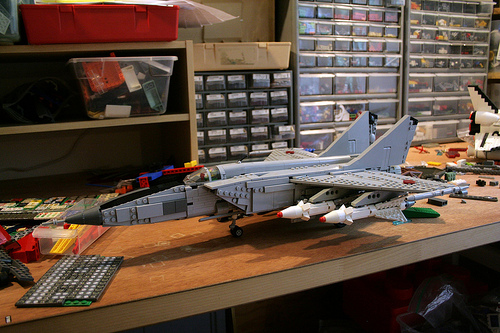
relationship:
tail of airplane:
[460, 79, 499, 155] [463, 83, 499, 154]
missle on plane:
[316, 200, 410, 228] [62, 108, 471, 239]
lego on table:
[14, 245, 125, 312] [2, 145, 499, 330]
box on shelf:
[68, 51, 179, 120] [0, 43, 202, 170]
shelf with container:
[0, 43, 202, 170] [17, 0, 182, 43]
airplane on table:
[463, 83, 499, 154] [2, 145, 499, 330]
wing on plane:
[291, 170, 459, 194] [62, 108, 471, 239]